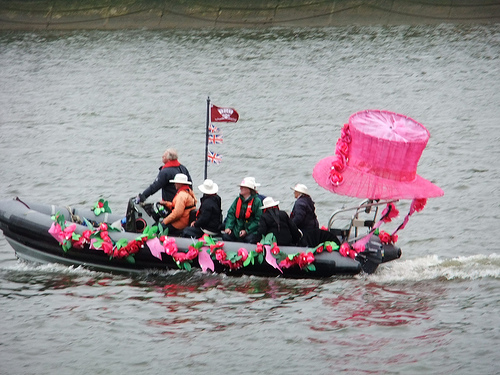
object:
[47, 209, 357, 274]
decorations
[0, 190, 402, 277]
boat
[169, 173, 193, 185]
hat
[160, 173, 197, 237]
woman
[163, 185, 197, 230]
jacket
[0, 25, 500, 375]
water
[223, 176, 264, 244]
woman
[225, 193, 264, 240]
coat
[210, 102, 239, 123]
flag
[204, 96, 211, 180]
pole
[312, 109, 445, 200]
hat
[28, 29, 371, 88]
ripples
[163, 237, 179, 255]
flower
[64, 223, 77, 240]
flower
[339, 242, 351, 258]
flower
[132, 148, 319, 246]
people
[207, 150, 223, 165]
flag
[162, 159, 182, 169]
scarf